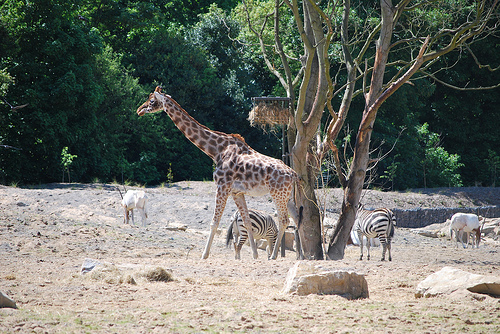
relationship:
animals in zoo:
[135, 86, 396, 260] [0, 8, 497, 329]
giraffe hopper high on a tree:
[248, 95, 295, 129] [217, 2, 498, 259]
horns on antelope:
[475, 210, 485, 227] [447, 212, 482, 246]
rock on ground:
[280, 256, 370, 302] [0, 181, 496, 328]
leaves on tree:
[217, 4, 477, 65] [245, 2, 492, 260]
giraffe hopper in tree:
[239, 90, 313, 140] [269, 38, 339, 279]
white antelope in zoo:
[114, 182, 150, 228] [12, 15, 474, 322]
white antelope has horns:
[103, 174, 156, 249] [110, 179, 133, 199]